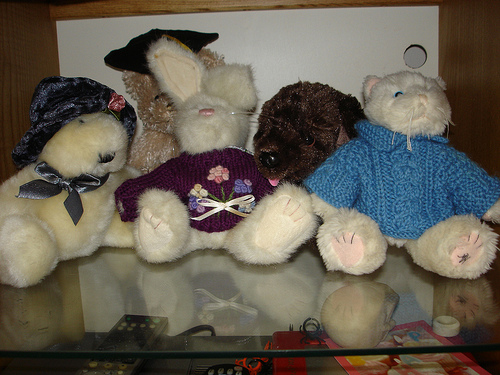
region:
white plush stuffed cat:
[307, 72, 499, 279]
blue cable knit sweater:
[307, 122, 497, 237]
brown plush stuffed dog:
[253, 81, 365, 188]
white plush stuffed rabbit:
[113, 43, 315, 265]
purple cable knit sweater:
[116, 152, 274, 222]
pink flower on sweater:
[206, 164, 231, 184]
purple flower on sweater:
[234, 177, 253, 194]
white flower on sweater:
[189, 182, 207, 198]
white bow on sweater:
[191, 193, 253, 221]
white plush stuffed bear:
[3, 77, 145, 290]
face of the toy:
[223, 71, 370, 196]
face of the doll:
[361, 52, 457, 146]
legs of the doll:
[259, 205, 400, 280]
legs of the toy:
[323, 214, 498, 284]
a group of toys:
[26, 68, 496, 250]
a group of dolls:
[15, 48, 495, 280]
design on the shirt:
[191, 197, 261, 240]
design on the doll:
[173, 152, 258, 223]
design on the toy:
[186, 162, 271, 230]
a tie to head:
[29, 160, 124, 240]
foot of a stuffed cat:
[313, 207, 383, 277]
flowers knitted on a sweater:
[176, 156, 253, 221]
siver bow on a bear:
[19, 164, 98, 219]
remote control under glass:
[73, 272, 178, 374]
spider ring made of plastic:
[298, 312, 327, 348]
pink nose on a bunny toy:
[196, 101, 221, 126]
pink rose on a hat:
[101, 91, 135, 113]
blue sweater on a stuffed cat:
[341, 127, 471, 224]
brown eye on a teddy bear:
[294, 119, 327, 166]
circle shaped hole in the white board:
[393, 34, 435, 75]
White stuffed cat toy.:
[301, 66, 498, 279]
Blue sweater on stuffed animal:
[301, 118, 498, 238]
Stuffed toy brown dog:
[250, 73, 372, 190]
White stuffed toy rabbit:
[116, 35, 322, 273]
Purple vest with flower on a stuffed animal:
[107, 148, 278, 237]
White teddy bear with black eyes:
[0, 73, 142, 289]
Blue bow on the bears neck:
[12, 160, 107, 223]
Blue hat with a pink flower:
[11, 68, 141, 170]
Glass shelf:
[3, 239, 498, 361]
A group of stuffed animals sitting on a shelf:
[3, 38, 498, 290]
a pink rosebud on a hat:
[107, 93, 126, 114]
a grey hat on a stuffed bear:
[12, 74, 137, 170]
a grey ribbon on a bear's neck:
[14, 163, 108, 216]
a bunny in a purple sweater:
[114, 39, 317, 264]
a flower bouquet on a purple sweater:
[187, 166, 255, 219]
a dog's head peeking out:
[254, 80, 366, 190]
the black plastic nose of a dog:
[260, 149, 280, 165]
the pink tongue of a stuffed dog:
[266, 177, 281, 188]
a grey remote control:
[75, 307, 171, 373]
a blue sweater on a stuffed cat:
[308, 118, 496, 231]